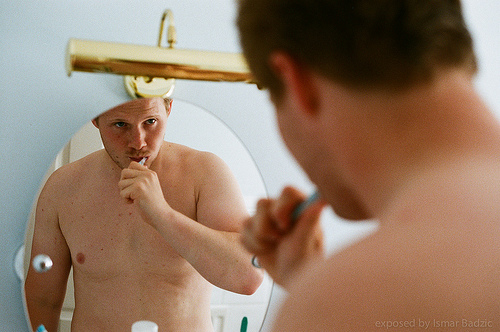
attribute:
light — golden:
[62, 34, 258, 84]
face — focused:
[94, 92, 172, 177]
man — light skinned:
[3, 86, 289, 323]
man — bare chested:
[281, 86, 489, 330]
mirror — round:
[21, 94, 278, 330]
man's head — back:
[211, 0, 498, 202]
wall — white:
[16, 23, 42, 120]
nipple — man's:
[59, 241, 94, 273]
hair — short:
[233, 0, 484, 108]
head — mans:
[236, 2, 494, 222]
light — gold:
[64, 7, 259, 100]